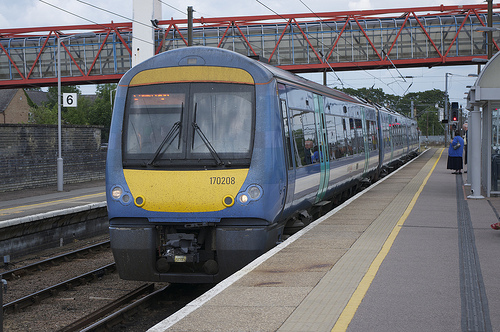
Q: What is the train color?
A: Blue and yellow.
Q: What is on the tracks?
A: A train.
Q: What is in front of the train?
A: Two front lights.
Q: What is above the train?
A: A gangway.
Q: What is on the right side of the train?
A: A yellow line.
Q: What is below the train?
A: It's tracks.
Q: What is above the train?
A: A red walkway.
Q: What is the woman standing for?
A: A train.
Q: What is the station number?
A: It's six.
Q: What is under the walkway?
A: A train.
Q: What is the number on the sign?
A: 6.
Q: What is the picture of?
A: Train.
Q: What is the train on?
A: Tracks.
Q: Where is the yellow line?
A: Platform.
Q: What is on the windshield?
A: Wipers.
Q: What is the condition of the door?
A: Closed.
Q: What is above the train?
A: Walkway.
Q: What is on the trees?
A: Leaves.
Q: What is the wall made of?
A: Brick.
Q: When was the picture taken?
A: On a cloudy day.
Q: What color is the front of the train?
A: Blue and yellow.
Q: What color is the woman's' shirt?
A: Blue.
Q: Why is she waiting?
A: For a train.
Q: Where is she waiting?
A: Train station.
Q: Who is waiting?
A: A woman.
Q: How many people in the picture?
A: One.